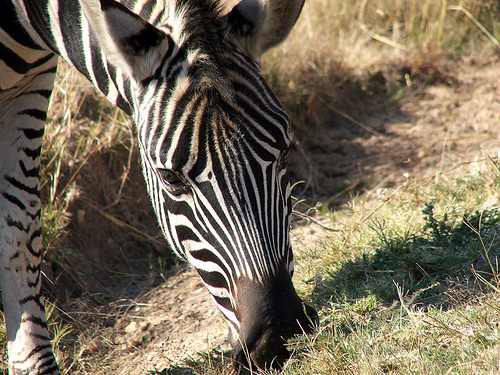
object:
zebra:
[0, 0, 319, 374]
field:
[0, 0, 499, 374]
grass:
[143, 149, 500, 375]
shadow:
[301, 211, 499, 311]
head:
[78, 0, 324, 374]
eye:
[156, 167, 186, 192]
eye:
[273, 142, 298, 170]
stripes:
[190, 180, 248, 279]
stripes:
[156, 83, 200, 171]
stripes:
[231, 92, 288, 152]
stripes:
[55, 0, 92, 83]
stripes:
[0, 174, 42, 203]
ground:
[0, 0, 499, 371]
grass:
[0, 1, 499, 374]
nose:
[228, 305, 321, 375]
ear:
[76, 0, 174, 84]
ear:
[220, 0, 306, 54]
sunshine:
[303, 0, 500, 287]